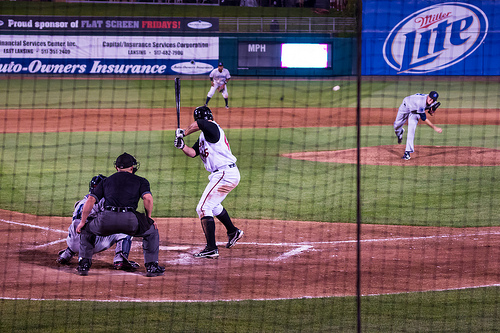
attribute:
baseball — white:
[332, 84, 341, 91]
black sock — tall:
[198, 217, 220, 256]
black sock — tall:
[215, 207, 238, 239]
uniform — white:
[186, 116, 246, 213]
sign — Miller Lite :
[363, 1, 497, 76]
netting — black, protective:
[2, 0, 499, 333]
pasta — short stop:
[390, 87, 451, 167]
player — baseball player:
[173, 105, 245, 260]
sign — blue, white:
[2, 16, 222, 82]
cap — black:
[112, 149, 140, 173]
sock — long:
[190, 214, 222, 257]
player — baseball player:
[139, 73, 279, 265]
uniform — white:
[183, 121, 247, 221]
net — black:
[268, 83, 405, 279]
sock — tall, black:
[201, 215, 217, 252]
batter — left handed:
[168, 101, 262, 260]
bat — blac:
[172, 75, 182, 145]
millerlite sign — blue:
[363, 1, 484, 71]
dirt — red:
[219, 181, 228, 193]